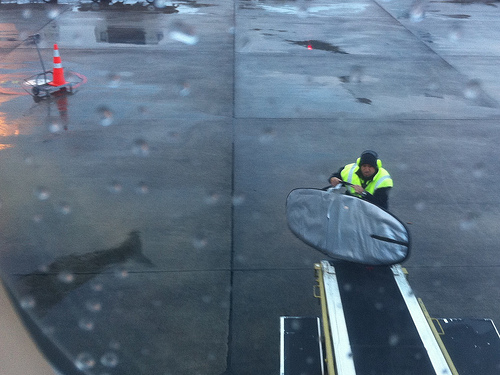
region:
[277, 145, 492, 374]
airport employee lifting silver bag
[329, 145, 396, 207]
airport employee wearing fluorescent vest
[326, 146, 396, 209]
airport worker wearing dark knit cap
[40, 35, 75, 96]
one orange cone with reflective stripes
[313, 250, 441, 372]
black airport conveyor belt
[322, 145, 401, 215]
one male worker wearing black coat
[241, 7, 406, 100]
one puddle on wet black pavement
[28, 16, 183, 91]
orange cone in front of large puddle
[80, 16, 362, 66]
two puddles on black pavement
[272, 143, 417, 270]
man lifting oval silver bag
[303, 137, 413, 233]
this is a person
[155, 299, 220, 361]
the person is in water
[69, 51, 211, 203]
the person is in water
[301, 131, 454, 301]
the person is in water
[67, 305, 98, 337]
this is a small circle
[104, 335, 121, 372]
this is a small circle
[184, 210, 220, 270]
this is a small circle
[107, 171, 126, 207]
this is a small circle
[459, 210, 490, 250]
this is a small circle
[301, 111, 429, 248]
This is a person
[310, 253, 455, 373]
black conveyor belt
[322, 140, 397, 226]
man loading up luggage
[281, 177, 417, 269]
long grey piece of luggage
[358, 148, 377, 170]
black cap on man's head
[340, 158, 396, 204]
yellow safety vest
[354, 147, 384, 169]
earmuffs on man's head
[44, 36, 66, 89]
orange and white traffic cone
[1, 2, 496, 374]
dark wet paved area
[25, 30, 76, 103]
dolly holding a traffic cone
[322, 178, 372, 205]
strap on a grey bag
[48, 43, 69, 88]
orange traffic cone is wet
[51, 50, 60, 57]
gray stripe on traffic cone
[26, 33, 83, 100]
traffic cone on a hand cart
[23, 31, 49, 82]
black handle of hand cart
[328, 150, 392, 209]
man wearing a black knit hat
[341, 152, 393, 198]
man wearing a yellow safety vest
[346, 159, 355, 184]
reflective stripe on safety vest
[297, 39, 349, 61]
puddle on the pavement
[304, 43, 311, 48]
red light reflected in the puddle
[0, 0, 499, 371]
pavement is black